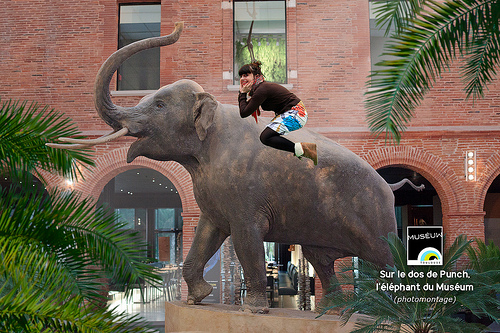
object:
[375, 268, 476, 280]
writing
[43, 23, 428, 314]
statue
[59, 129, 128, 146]
tusk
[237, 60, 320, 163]
woman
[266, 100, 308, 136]
shorts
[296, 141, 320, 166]
boots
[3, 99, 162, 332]
tree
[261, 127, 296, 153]
leggings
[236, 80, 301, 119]
shirt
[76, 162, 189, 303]
doorway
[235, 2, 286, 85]
window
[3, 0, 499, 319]
building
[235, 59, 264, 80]
hair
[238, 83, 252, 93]
hand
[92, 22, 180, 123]
trunk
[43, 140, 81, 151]
tusk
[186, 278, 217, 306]
foot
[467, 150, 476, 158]
light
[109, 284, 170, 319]
floor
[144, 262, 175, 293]
table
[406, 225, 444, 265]
sign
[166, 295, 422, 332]
block